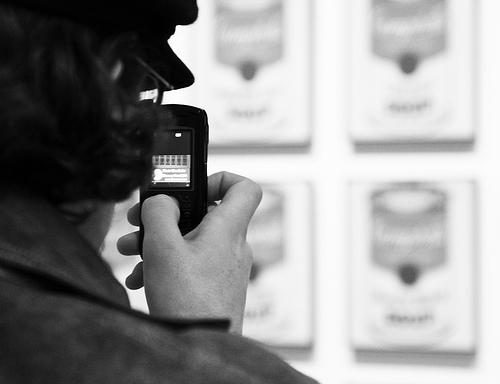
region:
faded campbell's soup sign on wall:
[344, 164, 474, 360]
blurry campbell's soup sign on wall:
[205, 166, 326, 353]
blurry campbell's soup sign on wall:
[337, 0, 478, 153]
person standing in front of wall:
[4, 4, 311, 381]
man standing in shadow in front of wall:
[1, 0, 258, 378]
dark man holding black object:
[2, 6, 262, 378]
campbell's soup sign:
[347, 172, 474, 367]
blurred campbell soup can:
[351, 2, 478, 149]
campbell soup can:
[368, 182, 463, 350]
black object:
[130, 86, 218, 221]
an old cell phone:
[144, 99, 214, 279]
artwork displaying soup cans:
[342, 8, 486, 375]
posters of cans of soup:
[328, 3, 498, 365]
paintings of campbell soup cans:
[347, 8, 498, 350]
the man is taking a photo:
[2, 3, 325, 380]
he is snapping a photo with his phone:
[6, 0, 301, 377]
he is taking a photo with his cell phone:
[2, 0, 319, 377]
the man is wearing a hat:
[17, 0, 329, 382]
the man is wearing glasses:
[2, 3, 298, 371]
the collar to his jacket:
[1, 203, 223, 333]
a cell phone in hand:
[134, 106, 242, 253]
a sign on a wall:
[331, 165, 486, 366]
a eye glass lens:
[118, 66, 175, 117]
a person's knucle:
[236, 175, 268, 217]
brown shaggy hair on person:
[0, 5, 160, 204]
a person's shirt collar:
[4, 213, 138, 315]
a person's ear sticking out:
[105, 60, 125, 93]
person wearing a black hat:
[18, 0, 244, 95]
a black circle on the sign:
[380, 52, 442, 84]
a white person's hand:
[117, 170, 269, 362]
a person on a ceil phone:
[32, 0, 272, 301]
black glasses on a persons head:
[85, 45, 195, 135]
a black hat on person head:
[55, 0, 237, 80]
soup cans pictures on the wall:
[322, 151, 452, 351]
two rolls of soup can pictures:
[220, 0, 470, 337]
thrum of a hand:
[137, 186, 177, 271]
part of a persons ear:
[97, 55, 132, 125]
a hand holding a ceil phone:
[118, 102, 250, 330]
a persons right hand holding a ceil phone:
[133, 99, 289, 341]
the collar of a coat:
[2, 203, 239, 335]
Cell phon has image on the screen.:
[139, 103, 210, 258]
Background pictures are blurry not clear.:
[101, 0, 487, 370]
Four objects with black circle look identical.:
[212, 0, 448, 282]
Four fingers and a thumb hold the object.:
[116, 169, 266, 339]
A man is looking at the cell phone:
[1, 0, 318, 382]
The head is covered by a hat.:
[1, 0, 199, 92]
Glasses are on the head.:
[117, 51, 177, 113]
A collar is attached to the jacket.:
[0, 180, 230, 335]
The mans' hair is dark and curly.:
[1, 6, 172, 212]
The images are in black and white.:
[0, 0, 487, 374]